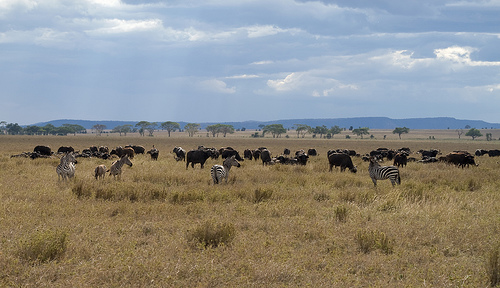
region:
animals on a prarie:
[19, 124, 494, 201]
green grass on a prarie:
[189, 219, 251, 254]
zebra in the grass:
[208, 155, 247, 187]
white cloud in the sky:
[412, 42, 480, 74]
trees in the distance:
[161, 116, 295, 136]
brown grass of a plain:
[81, 209, 166, 286]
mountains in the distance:
[68, 109, 125, 128]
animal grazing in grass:
[326, 142, 358, 183]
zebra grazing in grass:
[87, 163, 113, 185]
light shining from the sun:
[88, 1, 128, 14]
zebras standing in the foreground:
[52, 149, 402, 190]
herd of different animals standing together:
[23, 125, 488, 200]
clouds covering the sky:
[2, 0, 499, 98]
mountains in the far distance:
[33, 117, 497, 130]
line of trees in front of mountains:
[4, 117, 499, 140]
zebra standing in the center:
[202, 149, 239, 181]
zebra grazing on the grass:
[89, 162, 106, 182]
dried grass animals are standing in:
[1, 133, 496, 287]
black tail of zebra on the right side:
[393, 170, 405, 182]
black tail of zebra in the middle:
[210, 163, 222, 183]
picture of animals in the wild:
[15, 20, 489, 263]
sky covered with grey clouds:
[59, 0, 471, 95]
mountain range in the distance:
[30, 98, 494, 132]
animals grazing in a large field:
[21, 110, 483, 209]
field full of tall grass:
[37, 184, 457, 266]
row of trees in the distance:
[12, 116, 484, 141]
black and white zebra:
[352, 150, 407, 195]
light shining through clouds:
[88, 0, 153, 44]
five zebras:
[54, 150, 412, 190]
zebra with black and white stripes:
[357, 143, 405, 184]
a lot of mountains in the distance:
[30, 117, 479, 125]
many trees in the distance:
[3, 122, 489, 141]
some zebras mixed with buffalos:
[18, 139, 498, 191]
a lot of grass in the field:
[11, 206, 496, 287]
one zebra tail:
[211, 167, 217, 181]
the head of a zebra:
[61, 151, 78, 166]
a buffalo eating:
[326, 154, 358, 174]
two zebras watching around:
[211, 154, 404, 189]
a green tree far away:
[465, 126, 482, 143]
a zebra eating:
[92, 164, 104, 184]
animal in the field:
[313, 148, 366, 178]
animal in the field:
[360, 159, 405, 182]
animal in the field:
[256, 149, 271, 164]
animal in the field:
[205, 160, 234, 185]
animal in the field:
[175, 150, 214, 162]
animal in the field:
[143, 150, 161, 166]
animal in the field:
[111, 156, 135, 175]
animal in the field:
[86, 160, 114, 180]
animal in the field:
[427, 153, 470, 174]